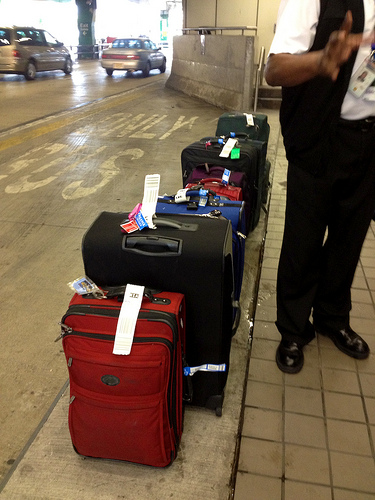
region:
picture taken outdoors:
[67, 21, 352, 166]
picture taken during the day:
[33, 299, 343, 479]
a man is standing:
[255, 66, 374, 390]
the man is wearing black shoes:
[273, 342, 374, 366]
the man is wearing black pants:
[280, 217, 366, 327]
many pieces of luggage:
[80, 224, 198, 464]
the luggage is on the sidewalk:
[131, 205, 209, 462]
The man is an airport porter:
[280, 208, 366, 370]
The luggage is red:
[110, 414, 132, 438]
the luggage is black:
[99, 235, 116, 261]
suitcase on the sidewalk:
[53, 278, 176, 463]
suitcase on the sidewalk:
[178, 222, 230, 405]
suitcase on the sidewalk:
[160, 196, 244, 212]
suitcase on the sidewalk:
[186, 177, 233, 195]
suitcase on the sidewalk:
[190, 173, 239, 180]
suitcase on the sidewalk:
[177, 137, 246, 164]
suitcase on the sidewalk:
[221, 110, 269, 132]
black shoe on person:
[327, 318, 367, 355]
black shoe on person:
[274, 339, 312, 382]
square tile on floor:
[287, 414, 330, 448]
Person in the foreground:
[258, 0, 374, 374]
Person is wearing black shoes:
[259, 302, 374, 376]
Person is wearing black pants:
[271, 152, 370, 341]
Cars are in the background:
[0, 11, 169, 89]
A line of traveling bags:
[57, 76, 279, 472]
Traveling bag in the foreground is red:
[37, 266, 210, 488]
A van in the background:
[1, 19, 78, 89]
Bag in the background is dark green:
[212, 100, 275, 148]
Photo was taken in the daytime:
[8, 5, 367, 492]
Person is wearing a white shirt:
[263, 0, 373, 126]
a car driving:
[101, 37, 165, 75]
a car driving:
[0, 25, 72, 73]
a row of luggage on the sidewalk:
[52, 112, 275, 494]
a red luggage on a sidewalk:
[65, 279, 190, 467]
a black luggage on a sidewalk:
[81, 209, 234, 279]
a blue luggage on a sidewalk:
[154, 198, 242, 218]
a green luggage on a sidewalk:
[220, 113, 269, 140]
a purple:
[188, 167, 245, 186]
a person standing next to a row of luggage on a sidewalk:
[268, 0, 374, 374]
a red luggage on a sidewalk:
[187, 181, 243, 198]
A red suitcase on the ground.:
[59, 259, 203, 433]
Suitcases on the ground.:
[148, 94, 266, 309]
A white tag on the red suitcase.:
[118, 278, 139, 346]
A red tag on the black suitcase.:
[109, 204, 142, 231]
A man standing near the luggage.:
[260, 0, 359, 243]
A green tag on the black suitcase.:
[229, 139, 250, 165]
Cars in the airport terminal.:
[58, 23, 185, 85]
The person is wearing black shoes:
[279, 328, 372, 375]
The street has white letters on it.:
[48, 99, 177, 199]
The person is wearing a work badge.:
[345, 55, 373, 111]